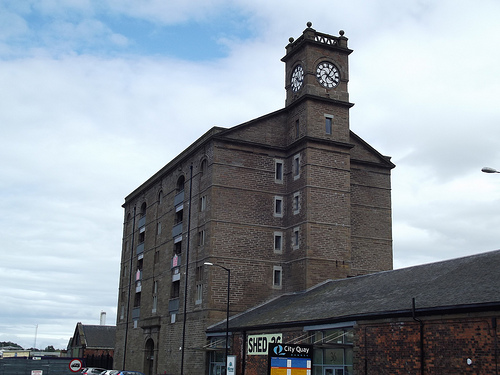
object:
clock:
[318, 60, 340, 88]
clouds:
[0, 0, 499, 350]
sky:
[0, 0, 500, 351]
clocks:
[288, 61, 304, 93]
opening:
[274, 158, 287, 185]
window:
[322, 117, 333, 135]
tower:
[283, 21, 352, 292]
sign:
[243, 333, 279, 355]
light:
[202, 261, 228, 274]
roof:
[207, 249, 499, 334]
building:
[113, 21, 395, 372]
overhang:
[135, 314, 159, 331]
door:
[140, 338, 156, 375]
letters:
[260, 336, 267, 353]